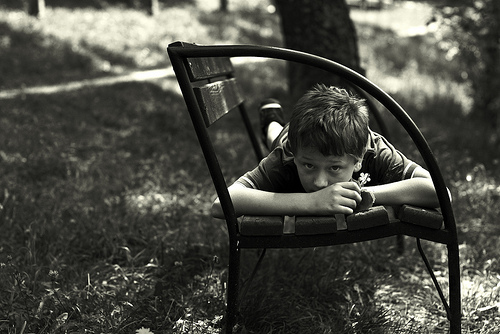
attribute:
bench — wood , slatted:
[183, 55, 448, 271]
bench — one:
[171, 36, 471, 327]